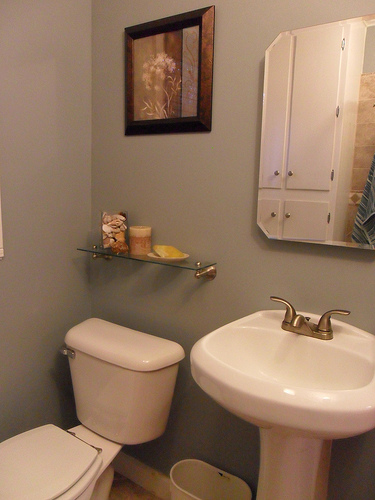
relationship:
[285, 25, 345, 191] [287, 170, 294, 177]
cabinet has door handle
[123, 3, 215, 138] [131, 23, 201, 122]
frame on sides of picture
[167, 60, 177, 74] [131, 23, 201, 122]
flower printed in picture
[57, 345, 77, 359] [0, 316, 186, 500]
handle on side of toilet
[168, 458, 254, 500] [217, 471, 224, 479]
waste basket has spot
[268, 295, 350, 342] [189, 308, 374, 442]
faucet on top of sink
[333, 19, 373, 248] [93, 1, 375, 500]
mirror hanging on wall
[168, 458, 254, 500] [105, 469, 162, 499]
waste basket sitting on floor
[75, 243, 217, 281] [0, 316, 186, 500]
shelf above toilet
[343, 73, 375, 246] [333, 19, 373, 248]
reflection shown in mirror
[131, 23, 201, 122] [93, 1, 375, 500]
picture hanging on wall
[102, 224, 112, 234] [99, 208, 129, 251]
shell inside of jar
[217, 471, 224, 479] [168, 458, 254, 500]
spot inside waste basket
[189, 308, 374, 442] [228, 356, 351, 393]
sink has bottom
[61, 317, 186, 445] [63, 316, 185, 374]
tank has top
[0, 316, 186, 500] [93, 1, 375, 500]
toilet near wall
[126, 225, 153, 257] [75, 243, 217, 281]
candle sitting on shelf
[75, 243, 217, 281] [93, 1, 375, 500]
shelf mounted on wall